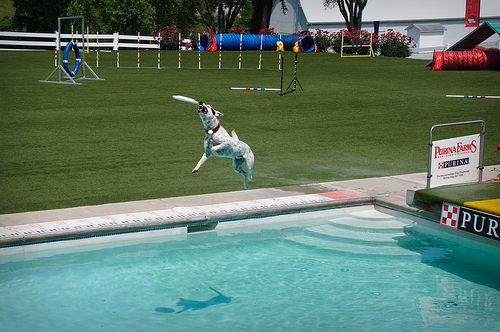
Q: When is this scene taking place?
A: Daytime.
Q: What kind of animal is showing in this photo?
A: Dog.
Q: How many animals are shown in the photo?
A: One.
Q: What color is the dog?
A: White and gray.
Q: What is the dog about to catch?
A: Frisbee.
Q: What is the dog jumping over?
A: Pool.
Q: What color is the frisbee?
A: White.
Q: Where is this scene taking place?
A: At the pool.